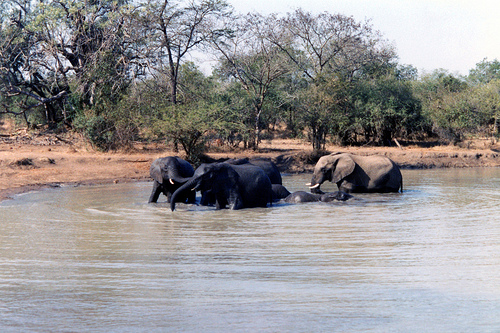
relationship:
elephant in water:
[305, 151, 405, 196] [3, 213, 500, 332]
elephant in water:
[172, 164, 274, 212] [3, 213, 500, 332]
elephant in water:
[147, 157, 193, 208] [3, 213, 500, 332]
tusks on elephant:
[310, 184, 320, 189] [305, 151, 405, 196]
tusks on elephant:
[306, 182, 311, 187] [305, 151, 405, 196]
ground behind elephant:
[3, 156, 147, 197] [147, 157, 193, 208]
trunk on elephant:
[167, 175, 200, 212] [172, 164, 274, 212]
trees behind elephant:
[0, 2, 499, 137] [305, 151, 405, 196]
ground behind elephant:
[3, 156, 147, 197] [305, 151, 405, 196]